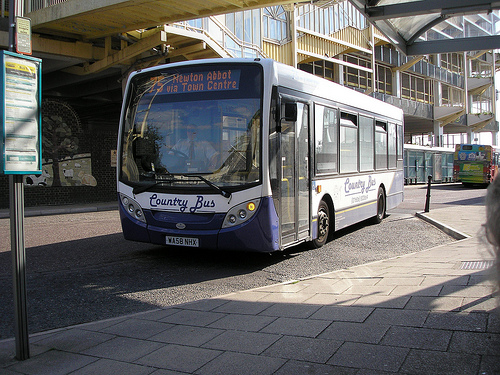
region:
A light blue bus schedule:
[0, 49, 43, 175]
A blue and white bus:
[114, 55, 405, 255]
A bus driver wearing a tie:
[167, 122, 220, 172]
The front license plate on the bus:
[164, 233, 200, 248]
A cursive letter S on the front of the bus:
[208, 199, 217, 208]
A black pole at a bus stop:
[422, 173, 433, 212]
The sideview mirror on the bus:
[275, 100, 297, 131]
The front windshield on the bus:
[117, 60, 263, 194]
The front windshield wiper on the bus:
[152, 170, 231, 198]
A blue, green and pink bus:
[451, 141, 499, 187]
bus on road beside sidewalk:
[103, 50, 416, 265]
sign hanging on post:
[2, 44, 52, 189]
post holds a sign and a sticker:
[13, 20, 30, 357]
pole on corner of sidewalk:
[420, 168, 435, 214]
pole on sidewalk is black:
[423, 173, 434, 215]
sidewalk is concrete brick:
[1, 200, 494, 372]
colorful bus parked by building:
[445, 133, 499, 192]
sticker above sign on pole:
[11, 12, 33, 53]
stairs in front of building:
[146, 8, 285, 64]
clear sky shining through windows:
[414, 80, 499, 165]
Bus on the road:
[94, 50, 420, 251]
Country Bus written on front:
[121, 186, 233, 211]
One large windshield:
[114, 74, 274, 197]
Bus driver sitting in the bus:
[167, 125, 224, 172]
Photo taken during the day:
[17, 14, 492, 363]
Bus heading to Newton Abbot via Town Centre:
[144, 67, 254, 102]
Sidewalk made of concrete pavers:
[69, 254, 497, 364]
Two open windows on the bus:
[335, 109, 396, 134]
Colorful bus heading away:
[442, 136, 495, 197]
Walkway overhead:
[34, 0, 262, 35]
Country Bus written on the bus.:
[145, 190, 222, 215]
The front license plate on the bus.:
[158, 227, 205, 253]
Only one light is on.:
[217, 196, 263, 234]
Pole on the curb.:
[421, 170, 438, 215]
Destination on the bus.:
[166, 63, 246, 98]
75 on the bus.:
[142, 72, 171, 95]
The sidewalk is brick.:
[36, 261, 497, 372]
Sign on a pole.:
[3, 49, 48, 355]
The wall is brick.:
[0, 103, 124, 210]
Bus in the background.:
[454, 140, 499, 191]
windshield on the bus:
[127, 98, 252, 185]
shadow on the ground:
[392, 273, 498, 320]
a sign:
[1, 51, 44, 181]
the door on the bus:
[280, 102, 307, 230]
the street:
[351, 226, 395, 263]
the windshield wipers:
[195, 172, 234, 192]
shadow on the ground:
[55, 238, 120, 293]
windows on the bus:
[338, 115, 393, 165]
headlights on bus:
[243, 200, 255, 215]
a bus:
[452, 141, 490, 185]